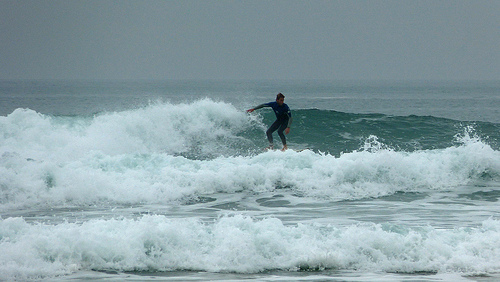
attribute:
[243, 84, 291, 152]
man — surfing, bare foot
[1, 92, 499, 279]
waves — crashing, rough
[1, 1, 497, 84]
sky — gray, blue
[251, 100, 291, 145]
wetsuit — black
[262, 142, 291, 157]
man's surfboard — hidden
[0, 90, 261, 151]
wave — white, large